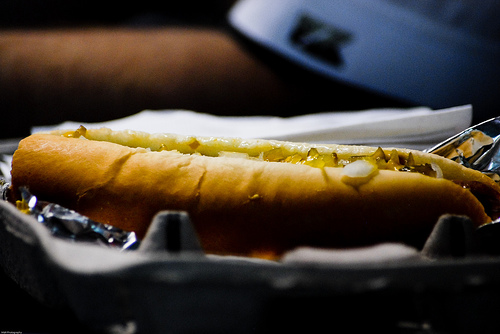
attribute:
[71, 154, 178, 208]
bun — golden, fresh, brown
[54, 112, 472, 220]
hotdog — sitting, meat, yummy, creamy, long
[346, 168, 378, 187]
onions — grilled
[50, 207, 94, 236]
wrapper — metallic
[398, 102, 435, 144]
paper — white, polythene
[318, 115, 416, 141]
napkin — white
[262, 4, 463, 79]
shirt — white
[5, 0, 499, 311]
picture — dark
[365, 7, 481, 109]
sleeve — black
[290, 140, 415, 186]
garnish — white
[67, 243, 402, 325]
tin — metal